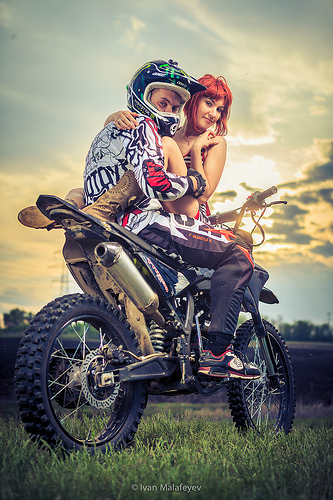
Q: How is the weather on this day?
A: It is cloudy.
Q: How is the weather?
A: It is cloudy.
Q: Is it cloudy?
A: Yes, it is cloudy.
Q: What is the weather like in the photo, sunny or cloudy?
A: It is cloudy.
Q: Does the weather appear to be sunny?
A: No, it is cloudy.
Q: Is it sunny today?
A: No, it is cloudy.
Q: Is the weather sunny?
A: No, it is cloudy.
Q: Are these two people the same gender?
A: No, they are both male and female.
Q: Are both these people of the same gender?
A: No, they are both male and female.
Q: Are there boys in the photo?
A: No, there are no boys.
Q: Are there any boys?
A: No, there are no boys.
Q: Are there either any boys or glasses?
A: No, there are no boys or glasses.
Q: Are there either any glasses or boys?
A: No, there are no boys or glasses.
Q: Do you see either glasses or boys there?
A: No, there are no boys or glasses.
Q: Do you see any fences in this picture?
A: No, there are no fences.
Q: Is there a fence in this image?
A: No, there are no fences.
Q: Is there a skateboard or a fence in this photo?
A: No, there are no fences or skateboards.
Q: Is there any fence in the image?
A: No, there are no fences.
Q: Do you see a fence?
A: No, there are no fences.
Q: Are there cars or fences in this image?
A: No, there are no fences or cars.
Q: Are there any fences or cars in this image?
A: No, there are no fences or cars.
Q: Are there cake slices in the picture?
A: No, there are no cake slices.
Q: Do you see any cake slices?
A: No, there are no cake slices.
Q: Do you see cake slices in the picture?
A: No, there are no cake slices.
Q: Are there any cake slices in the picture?
A: No, there are no cake slices.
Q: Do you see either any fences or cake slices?
A: No, there are no cake slices or fences.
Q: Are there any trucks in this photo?
A: No, there are no trucks.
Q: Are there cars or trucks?
A: No, there are no trucks or cars.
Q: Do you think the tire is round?
A: Yes, the tire is round.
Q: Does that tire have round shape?
A: Yes, the tire is round.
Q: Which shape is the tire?
A: The tire is round.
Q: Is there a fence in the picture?
A: No, there are no fences.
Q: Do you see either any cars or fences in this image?
A: No, there are no fences or cars.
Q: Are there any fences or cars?
A: No, there are no fences or cars.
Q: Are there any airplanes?
A: No, there are no airplanes.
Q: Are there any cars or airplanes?
A: No, there are no airplanes or cars.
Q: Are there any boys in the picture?
A: No, there are no boys.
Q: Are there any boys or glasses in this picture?
A: No, there are no boys or glasses.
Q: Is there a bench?
A: No, there are no benches.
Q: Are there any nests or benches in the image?
A: No, there are no benches or nests.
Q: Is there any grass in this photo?
A: Yes, there is grass.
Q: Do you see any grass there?
A: Yes, there is grass.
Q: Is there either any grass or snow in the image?
A: Yes, there is grass.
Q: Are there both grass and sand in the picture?
A: No, there is grass but no sand.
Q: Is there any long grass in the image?
A: Yes, there is long grass.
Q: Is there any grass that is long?
A: Yes, there is long grass.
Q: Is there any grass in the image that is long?
A: Yes, there is grass that is long.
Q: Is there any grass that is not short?
A: Yes, there is long grass.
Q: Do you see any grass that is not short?
A: Yes, there is long grass.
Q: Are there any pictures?
A: No, there are no pictures.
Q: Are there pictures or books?
A: No, there are no pictures or books.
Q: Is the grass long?
A: Yes, the grass is long.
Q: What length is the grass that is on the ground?
A: The grass is long.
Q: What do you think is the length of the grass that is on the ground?
A: The grass is long.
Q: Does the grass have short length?
A: No, the grass is long.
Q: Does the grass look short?
A: No, the grass is long.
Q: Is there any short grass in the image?
A: No, there is grass but it is long.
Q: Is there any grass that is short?
A: No, there is grass but it is long.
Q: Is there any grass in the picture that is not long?
A: No, there is grass but it is long.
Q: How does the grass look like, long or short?
A: The grass is long.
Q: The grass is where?
A: The grass is on the ground.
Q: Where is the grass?
A: The grass is on the ground.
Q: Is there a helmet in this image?
A: Yes, there is a helmet.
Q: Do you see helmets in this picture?
A: Yes, there is a helmet.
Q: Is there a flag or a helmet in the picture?
A: Yes, there is a helmet.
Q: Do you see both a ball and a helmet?
A: No, there is a helmet but no balls.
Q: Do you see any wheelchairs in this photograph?
A: No, there are no wheelchairs.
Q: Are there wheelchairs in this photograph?
A: No, there are no wheelchairs.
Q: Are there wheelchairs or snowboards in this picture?
A: No, there are no wheelchairs or snowboards.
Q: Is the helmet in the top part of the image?
A: Yes, the helmet is in the top of the image.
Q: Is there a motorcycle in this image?
A: Yes, there is a motorcycle.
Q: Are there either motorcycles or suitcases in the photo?
A: Yes, there is a motorcycle.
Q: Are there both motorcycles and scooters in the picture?
A: No, there is a motorcycle but no scooters.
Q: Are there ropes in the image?
A: No, there are no ropes.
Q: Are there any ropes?
A: No, there are no ropes.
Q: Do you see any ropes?
A: No, there are no ropes.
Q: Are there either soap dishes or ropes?
A: No, there are no ropes or soap dishes.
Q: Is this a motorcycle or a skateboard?
A: This is a motorcycle.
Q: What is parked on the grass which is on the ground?
A: The motorcycle is parked on the grass.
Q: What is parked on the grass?
A: The motorcycle is parked on the grass.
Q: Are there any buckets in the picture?
A: No, there are no buckets.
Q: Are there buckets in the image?
A: No, there are no buckets.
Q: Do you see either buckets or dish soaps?
A: No, there are no buckets or dish soaps.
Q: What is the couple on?
A: The couple is on the motorbike.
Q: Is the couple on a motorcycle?
A: Yes, the couple is on a motorcycle.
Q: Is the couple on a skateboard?
A: No, the couple is on a motorcycle.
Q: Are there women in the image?
A: Yes, there is a woman.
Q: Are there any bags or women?
A: Yes, there is a woman.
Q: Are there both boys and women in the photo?
A: No, there is a woman but no boys.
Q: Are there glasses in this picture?
A: No, there are no glasses.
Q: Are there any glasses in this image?
A: No, there are no glasses.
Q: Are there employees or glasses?
A: No, there are no glasses or employees.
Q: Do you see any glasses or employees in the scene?
A: No, there are no glasses or employees.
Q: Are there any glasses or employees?
A: No, there are no glasses or employees.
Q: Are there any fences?
A: No, there are no fences.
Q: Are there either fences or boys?
A: No, there are no fences or boys.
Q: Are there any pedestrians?
A: No, there are no pedestrians.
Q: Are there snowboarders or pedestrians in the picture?
A: No, there are no pedestrians or snowboarders.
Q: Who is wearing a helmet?
A: The man is wearing a helmet.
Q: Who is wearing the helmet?
A: The man is wearing a helmet.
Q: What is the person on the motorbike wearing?
A: The man is wearing a helmet.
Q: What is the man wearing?
A: The man is wearing a helmet.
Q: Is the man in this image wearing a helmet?
A: Yes, the man is wearing a helmet.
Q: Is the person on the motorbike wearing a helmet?
A: Yes, the man is wearing a helmet.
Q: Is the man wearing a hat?
A: No, the man is wearing a helmet.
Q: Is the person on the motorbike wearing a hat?
A: No, the man is wearing a helmet.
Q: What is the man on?
A: The man is on the motorbike.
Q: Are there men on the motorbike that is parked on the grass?
A: Yes, there is a man on the motorbike.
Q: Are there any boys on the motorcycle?
A: No, there is a man on the motorcycle.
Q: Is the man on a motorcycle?
A: Yes, the man is on a motorcycle.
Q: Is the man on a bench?
A: No, the man is on a motorcycle.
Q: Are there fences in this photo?
A: No, there are no fences.